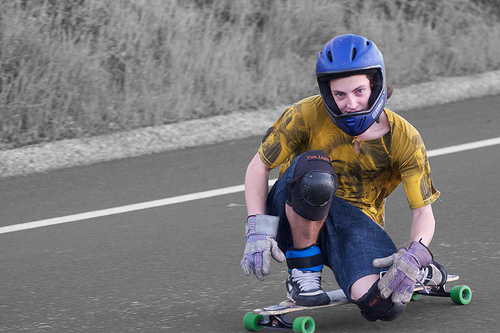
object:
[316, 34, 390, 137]
helmet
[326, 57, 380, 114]
head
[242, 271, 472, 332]
skateboard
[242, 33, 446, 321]
boy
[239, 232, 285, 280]
hand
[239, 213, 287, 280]
glove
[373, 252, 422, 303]
hand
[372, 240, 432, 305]
glove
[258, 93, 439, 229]
shirt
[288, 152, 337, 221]
knee pad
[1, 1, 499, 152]
weeds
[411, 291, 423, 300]
wheel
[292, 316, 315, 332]
wheel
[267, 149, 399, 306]
shorts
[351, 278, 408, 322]
knee pad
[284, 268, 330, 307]
shoe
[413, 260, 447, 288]
shoe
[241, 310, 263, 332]
wheel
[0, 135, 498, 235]
line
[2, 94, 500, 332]
road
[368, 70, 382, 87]
hair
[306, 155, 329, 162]
print